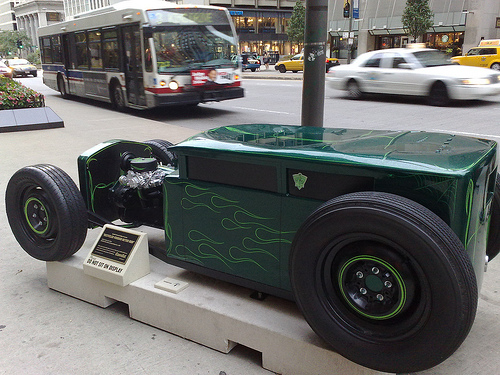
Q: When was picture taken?
A: Daytime.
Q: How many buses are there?
A: One.